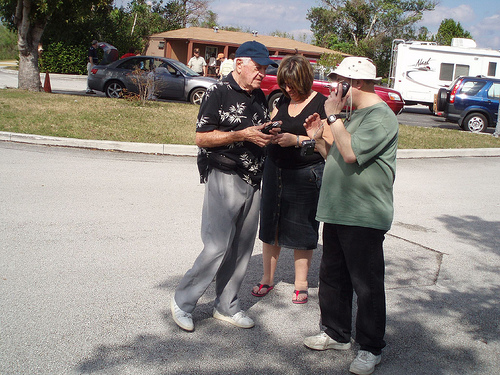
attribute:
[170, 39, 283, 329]
man — older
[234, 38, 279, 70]
hat — blue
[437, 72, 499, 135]
suv — blue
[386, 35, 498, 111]
rv — distant, white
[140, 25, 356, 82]
building — brown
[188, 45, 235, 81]
people — standing, interacting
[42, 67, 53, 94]
cone — orange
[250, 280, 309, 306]
sandals — pink, black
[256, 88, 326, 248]
dress — black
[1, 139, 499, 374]
pavement — road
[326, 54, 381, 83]
hat — white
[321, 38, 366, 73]
tree — green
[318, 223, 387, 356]
pants — black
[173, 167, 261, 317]
pants — gray, grey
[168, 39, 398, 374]
people — standing, interacting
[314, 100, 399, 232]
shirt — green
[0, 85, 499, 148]
grass — green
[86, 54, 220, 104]
car — grey, small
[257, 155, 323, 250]
skirt — denim